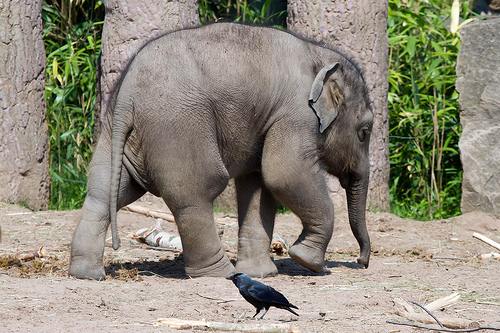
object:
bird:
[224, 273, 298, 321]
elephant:
[70, 23, 372, 282]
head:
[315, 46, 376, 180]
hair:
[319, 44, 371, 114]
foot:
[183, 246, 236, 278]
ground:
[2, 202, 498, 331]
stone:
[136, 228, 182, 252]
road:
[0, 211, 495, 329]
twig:
[387, 300, 498, 333]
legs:
[69, 141, 146, 280]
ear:
[309, 61, 343, 133]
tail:
[111, 73, 134, 249]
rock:
[456, 18, 499, 216]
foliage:
[388, 3, 464, 220]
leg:
[134, 124, 238, 277]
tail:
[276, 292, 299, 317]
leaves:
[43, 3, 103, 211]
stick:
[386, 300, 500, 331]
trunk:
[341, 178, 371, 267]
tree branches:
[388, 300, 498, 332]